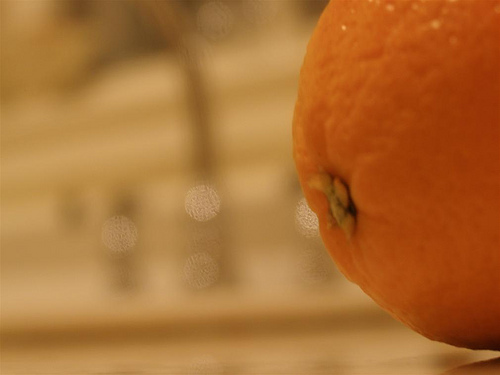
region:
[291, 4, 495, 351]
orange citrus fruit on counter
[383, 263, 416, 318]
skin of orange fruit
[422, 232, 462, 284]
skin of orange fruit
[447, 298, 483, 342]
skin of orange fruit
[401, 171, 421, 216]
skin of orange fruit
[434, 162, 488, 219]
skin of orange fruit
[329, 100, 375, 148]
skin of orange fruit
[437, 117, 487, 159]
skin of orange fruit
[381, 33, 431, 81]
skin of orange fruit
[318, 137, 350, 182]
skin of orange fruit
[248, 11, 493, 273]
an orange that is orange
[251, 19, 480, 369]
an orange that is fresh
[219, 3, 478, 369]
a fresh orange that is inside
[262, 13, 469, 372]
an orange that is inside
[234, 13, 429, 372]
a fresh orange inside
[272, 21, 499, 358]
an orange on a table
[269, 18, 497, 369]
a fresh orange on the table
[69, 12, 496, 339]
an orange in the kitchen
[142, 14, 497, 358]
a table with orange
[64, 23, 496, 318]
kitchen with orange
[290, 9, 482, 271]
this is an orange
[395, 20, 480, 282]
the orange is ripe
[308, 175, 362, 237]
this is the stalk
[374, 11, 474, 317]
the orange is big in size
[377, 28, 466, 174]
the orange has pores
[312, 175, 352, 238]
the stalk is small in size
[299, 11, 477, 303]
the orange is round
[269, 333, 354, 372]
this is the table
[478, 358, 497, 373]
this is the shadow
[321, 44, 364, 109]
part of a peel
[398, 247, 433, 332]
part of an orange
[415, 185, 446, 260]
part of a peel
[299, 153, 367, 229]
the navel of an orange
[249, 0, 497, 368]
an orange sitting on a counter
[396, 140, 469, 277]
textured surface of the orange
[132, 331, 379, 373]
beige surface of the counter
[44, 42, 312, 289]
chrome metal faucet of the sink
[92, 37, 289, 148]
white wood window sill behind the sink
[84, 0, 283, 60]
a window in the kitchen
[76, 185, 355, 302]
chrome metal levers of the faucet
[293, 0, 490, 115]
clean shiny surface of the orange